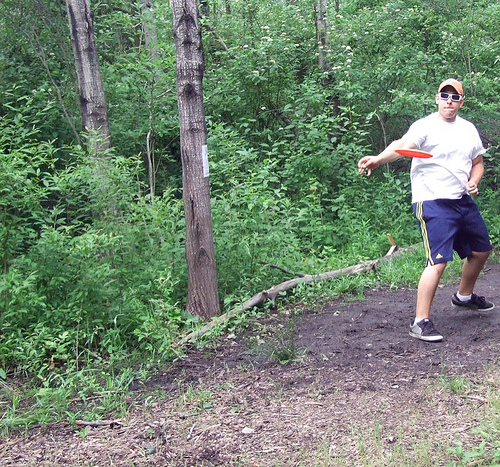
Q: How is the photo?
A: Clear.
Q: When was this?
A: Daytime.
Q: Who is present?
A: A man.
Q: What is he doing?
A: Playing.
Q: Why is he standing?
A: To play.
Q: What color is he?
A: White.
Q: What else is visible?
A: Trees.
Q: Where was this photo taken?
A: In a park.